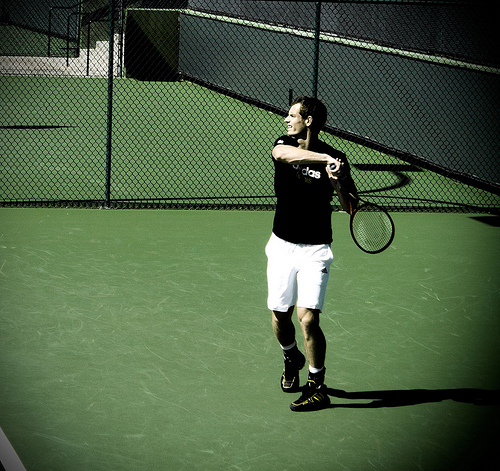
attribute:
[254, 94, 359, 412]
man — light-skinned, present, playing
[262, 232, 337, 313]
shorts — white, present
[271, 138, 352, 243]
t shirt — black, present, white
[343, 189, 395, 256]
racket — present, tennis, black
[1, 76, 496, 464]
ground — green, playing, tennis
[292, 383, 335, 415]
shoe — black, tennis, sport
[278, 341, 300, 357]
sock — white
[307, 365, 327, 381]
sock — white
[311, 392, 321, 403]
stripe — yellow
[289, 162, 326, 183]
adidas — white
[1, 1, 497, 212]
fence — chainlink, black, metal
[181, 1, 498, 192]
wall — green, back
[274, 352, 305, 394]
shoe — black, tennis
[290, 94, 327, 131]
hair — brown